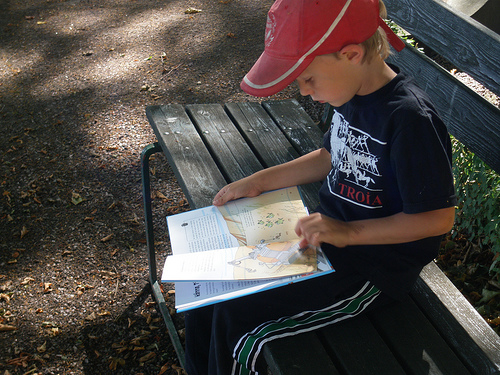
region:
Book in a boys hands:
[156, 174, 361, 362]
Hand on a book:
[290, 193, 351, 268]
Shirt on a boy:
[309, 70, 459, 309]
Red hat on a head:
[242, 4, 412, 116]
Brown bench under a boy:
[131, 73, 463, 369]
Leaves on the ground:
[8, 162, 146, 369]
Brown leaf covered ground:
[11, 16, 155, 306]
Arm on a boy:
[186, 126, 373, 208]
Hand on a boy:
[216, 161, 296, 223]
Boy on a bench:
[206, 12, 426, 347]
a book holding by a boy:
[166, 207, 329, 316]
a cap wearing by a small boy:
[237, 2, 403, 97]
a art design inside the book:
[221, 196, 307, 277]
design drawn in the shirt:
[331, 121, 387, 202]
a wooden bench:
[157, 95, 314, 160]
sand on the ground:
[1, 21, 141, 357]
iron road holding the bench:
[138, 149, 160, 289]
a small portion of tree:
[473, 5, 499, 20]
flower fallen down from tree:
[103, 231, 120, 256]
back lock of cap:
[377, 20, 406, 51]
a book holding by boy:
[171, 174, 319, 294]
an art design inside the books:
[226, 205, 303, 281]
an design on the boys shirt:
[326, 115, 386, 207]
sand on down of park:
[8, 173, 158, 370]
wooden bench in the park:
[172, 102, 324, 172]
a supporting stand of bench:
[139, 147, 164, 293]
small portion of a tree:
[472, 4, 499, 21]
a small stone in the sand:
[177, 4, 207, 18]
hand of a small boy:
[211, 149, 335, 199]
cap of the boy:
[237, 1, 386, 102]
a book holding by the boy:
[162, 178, 310, 299]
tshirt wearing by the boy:
[327, 103, 442, 273]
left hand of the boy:
[287, 212, 444, 249]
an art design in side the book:
[236, 204, 316, 275]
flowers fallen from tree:
[21, 262, 64, 310]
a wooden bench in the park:
[422, 18, 499, 115]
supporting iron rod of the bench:
[133, 150, 160, 281]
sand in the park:
[26, 14, 153, 371]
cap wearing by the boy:
[236, 5, 398, 98]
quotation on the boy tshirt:
[328, 124, 379, 210]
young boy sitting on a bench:
[152, 5, 463, 372]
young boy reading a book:
[137, 6, 474, 307]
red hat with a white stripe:
[225, 3, 421, 105]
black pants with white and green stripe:
[152, 223, 394, 372]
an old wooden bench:
[119, 4, 498, 364]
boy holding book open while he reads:
[140, 6, 444, 304]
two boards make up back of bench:
[375, 1, 499, 190]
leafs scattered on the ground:
[8, 64, 200, 366]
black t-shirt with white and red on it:
[303, 77, 475, 301]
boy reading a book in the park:
[42, 7, 483, 366]